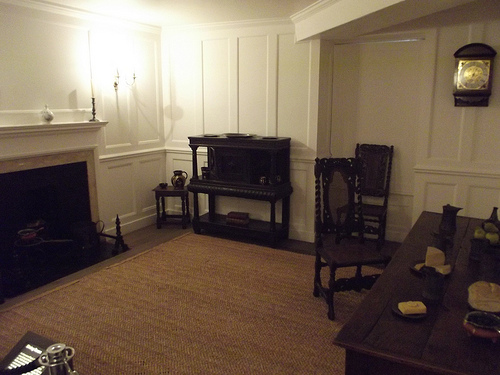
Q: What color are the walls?
A: White.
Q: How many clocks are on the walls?
A: One.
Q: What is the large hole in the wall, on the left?
A: A fireplace.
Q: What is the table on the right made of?
A: Wood.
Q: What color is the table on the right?
A: Brown.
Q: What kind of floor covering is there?
A: A rug.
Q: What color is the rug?
A: Brown.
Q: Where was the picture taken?
A: In a living room.